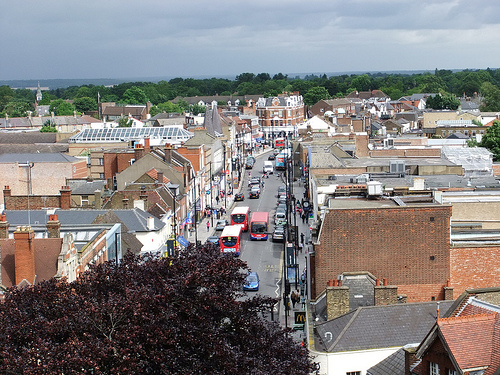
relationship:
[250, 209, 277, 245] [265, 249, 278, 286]
bus on street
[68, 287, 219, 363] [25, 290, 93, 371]
tree with purple leaves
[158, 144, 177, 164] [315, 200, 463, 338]
chimney on building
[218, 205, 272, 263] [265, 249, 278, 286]
buses on street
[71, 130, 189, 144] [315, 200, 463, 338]
roof of building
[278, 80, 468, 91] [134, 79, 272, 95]
grove of trees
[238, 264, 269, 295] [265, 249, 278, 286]
car on street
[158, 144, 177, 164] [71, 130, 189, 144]
chimney on roof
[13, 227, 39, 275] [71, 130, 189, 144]
chimney on roof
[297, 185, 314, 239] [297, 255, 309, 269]
people on sidewalk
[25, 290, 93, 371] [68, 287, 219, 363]
purple leaves on tree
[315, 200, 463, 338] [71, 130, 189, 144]
building with roof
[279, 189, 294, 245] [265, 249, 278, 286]
cars parked on street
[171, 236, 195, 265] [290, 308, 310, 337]
letter on sign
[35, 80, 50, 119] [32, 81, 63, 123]
steeple on church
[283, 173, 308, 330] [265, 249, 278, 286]
poles on street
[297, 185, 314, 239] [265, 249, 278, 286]
people on street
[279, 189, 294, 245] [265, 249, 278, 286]
cars on street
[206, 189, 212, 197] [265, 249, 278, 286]
signs on street